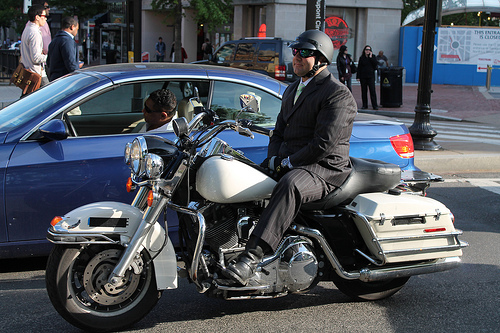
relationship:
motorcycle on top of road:
[45, 87, 468, 332] [1, 170, 499, 331]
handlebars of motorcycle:
[179, 104, 271, 145] [45, 87, 468, 332]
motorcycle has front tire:
[45, 87, 468, 332] [44, 241, 160, 332]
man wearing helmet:
[225, 28, 357, 286] [289, 26, 335, 63]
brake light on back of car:
[387, 130, 414, 162] [0, 63, 429, 264]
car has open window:
[0, 63, 429, 264] [31, 79, 211, 138]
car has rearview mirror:
[0, 63, 429, 264] [65, 75, 83, 100]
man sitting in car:
[129, 88, 178, 132] [0, 63, 429, 264]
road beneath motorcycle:
[1, 170, 499, 331] [45, 87, 468, 332]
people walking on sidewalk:
[9, 0, 85, 99] [415, 149, 499, 177]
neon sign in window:
[323, 14, 348, 49] [323, 4, 357, 64]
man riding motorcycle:
[225, 28, 357, 286] [45, 87, 468, 332]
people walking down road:
[9, 0, 85, 99] [1, 170, 499, 331]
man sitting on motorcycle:
[225, 28, 357, 286] [45, 87, 468, 332]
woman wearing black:
[355, 44, 380, 110] [355, 53, 379, 107]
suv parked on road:
[189, 35, 300, 88] [348, 106, 499, 157]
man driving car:
[129, 88, 178, 132] [0, 63, 429, 264]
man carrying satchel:
[14, 4, 51, 97] [13, 65, 42, 98]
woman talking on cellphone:
[355, 44, 380, 110] [367, 50, 373, 57]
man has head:
[129, 88, 178, 132] [140, 88, 176, 124]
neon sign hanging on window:
[323, 14, 348, 49] [323, 4, 357, 64]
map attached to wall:
[435, 26, 499, 67] [397, 25, 499, 90]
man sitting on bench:
[377, 48, 388, 70] [364, 66, 396, 77]